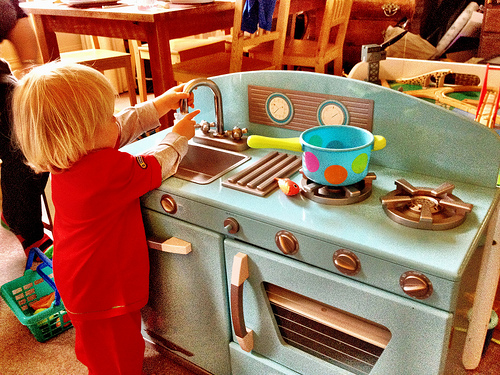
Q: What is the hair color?
A: Blonde.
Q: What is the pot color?
A: Blue.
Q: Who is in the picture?
A: A boy.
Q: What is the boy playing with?
A: A stove.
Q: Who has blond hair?
A: A boy.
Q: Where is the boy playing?
A: Playroom.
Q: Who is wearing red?
A: A boy.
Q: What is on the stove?
A: A pot.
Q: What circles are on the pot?
A: Polka dots.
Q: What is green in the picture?
A: The stove.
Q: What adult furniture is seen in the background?
A: A table.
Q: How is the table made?
A: Of wood.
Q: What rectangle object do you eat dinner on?
A: Table.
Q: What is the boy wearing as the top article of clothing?
A: Shirt.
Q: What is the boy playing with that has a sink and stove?
A: Play kitchen.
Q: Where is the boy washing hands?
A: Kitchen sink.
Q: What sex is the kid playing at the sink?
A: Male.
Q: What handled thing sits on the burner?
A: Pot.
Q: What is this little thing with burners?
A: Stove.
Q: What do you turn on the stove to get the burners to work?
A: Knobs.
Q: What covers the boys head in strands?
A: Hair.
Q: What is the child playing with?
A: The child is playing with a toy kitchen set.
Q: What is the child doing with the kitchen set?
A: The child is pretending to wash his/her hands.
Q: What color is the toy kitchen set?
A: Blue.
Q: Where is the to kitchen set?
A: In the kitchen.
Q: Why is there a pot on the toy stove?
A: To pretned to cook.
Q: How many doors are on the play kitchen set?
A: Two.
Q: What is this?
A: A toy kitchen set up.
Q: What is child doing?
A: Playing in the kitchen.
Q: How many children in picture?
A: One.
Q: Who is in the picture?
A: A child.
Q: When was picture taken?
A: During daylight.